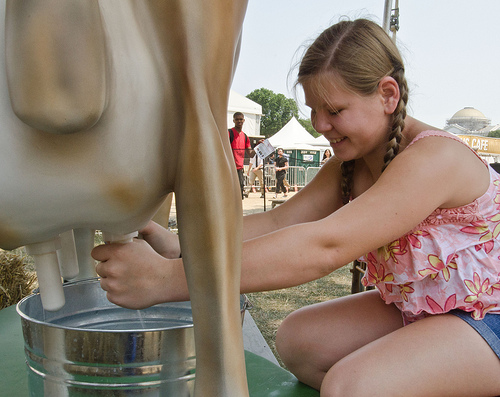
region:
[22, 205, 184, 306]
white plastic cow udders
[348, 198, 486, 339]
pink floral sleeveless top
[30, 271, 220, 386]
shiny metal milk pail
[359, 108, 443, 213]
girl with blonde braids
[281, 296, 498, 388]
blue denim jean shorts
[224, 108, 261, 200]
man with red shirt watching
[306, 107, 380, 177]
girl is smiling wide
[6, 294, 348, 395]
fake cow on green platform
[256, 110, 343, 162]
white tent in the background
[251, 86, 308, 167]
tall tree behind tents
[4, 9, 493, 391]
Fake cow you can milk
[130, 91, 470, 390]
Little girl practicing milking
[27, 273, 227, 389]
Tub for the milk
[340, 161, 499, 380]
Girl wearing floral blouse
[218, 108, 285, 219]
Man in red in background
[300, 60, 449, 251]
Girls hair is braided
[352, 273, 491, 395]
Girl wearing jean shorts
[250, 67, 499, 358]
Girl is squatting down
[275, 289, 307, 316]
Short grass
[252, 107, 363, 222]
White tents in the background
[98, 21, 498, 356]
A girl milking a cow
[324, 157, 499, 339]
Pink shirt with flowers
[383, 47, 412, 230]
Long braid behind ear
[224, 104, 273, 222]
Man in a red shirt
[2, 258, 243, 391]
Silver bucket below utters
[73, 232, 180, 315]
Hand squeezing and utter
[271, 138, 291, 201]
Man in a black outfit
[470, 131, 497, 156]
Cafe written in white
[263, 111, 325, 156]
White top to a canopy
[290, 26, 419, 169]
The girl has a smile on her face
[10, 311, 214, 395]
the bucket is silver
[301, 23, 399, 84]
the hair is brown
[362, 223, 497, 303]
the dress is color full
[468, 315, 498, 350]
the jeans is blue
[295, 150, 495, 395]
the girl is milking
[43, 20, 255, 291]
the cow is bronze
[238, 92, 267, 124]
the tent is white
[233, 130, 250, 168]
the top is red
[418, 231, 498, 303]
the shirt has dresses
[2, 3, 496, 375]
the scene was taken outdoors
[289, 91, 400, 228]
the girl is smiling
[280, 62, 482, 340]
the girl is smiling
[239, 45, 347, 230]
the girl is smiling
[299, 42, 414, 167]
the girl is smiling